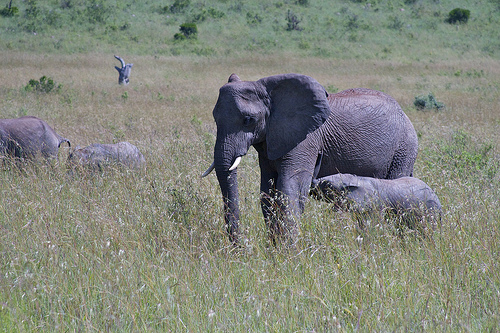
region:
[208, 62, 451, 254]
two elephants standing together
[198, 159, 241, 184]
white tusks of gray elephant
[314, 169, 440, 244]
baby elephant standing next to elephant with white tusks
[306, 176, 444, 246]
baby elephant nuzzling other elephant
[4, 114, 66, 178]
elephant next to gray rock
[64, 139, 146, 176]
large gray rock in field of long grass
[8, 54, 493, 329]
long grass elephants are walking through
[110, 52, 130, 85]
twisted trunk of dead tree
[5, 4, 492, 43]
field of green grass in background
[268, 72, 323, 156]
ear of larger elephant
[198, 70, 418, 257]
mother elephant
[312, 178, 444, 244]
baby elephant under mother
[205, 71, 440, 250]
mother nursing baby elephant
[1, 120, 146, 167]
two elephants hiding in the grass on left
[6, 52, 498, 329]
very tall grass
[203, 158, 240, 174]
tusks of mother elephant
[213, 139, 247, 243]
mother elephant's trunk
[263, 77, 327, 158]
mother elephant's big left ear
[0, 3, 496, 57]
green bushes on a hill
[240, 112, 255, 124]
the mother elephant's eye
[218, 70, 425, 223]
african elephant standing in grass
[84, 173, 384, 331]
tall green grass around elephants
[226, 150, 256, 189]
white ivory tusk on elephant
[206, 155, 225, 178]
white ivory tusk on elephant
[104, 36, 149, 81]
tree stump in tall grass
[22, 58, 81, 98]
green bushes in green grass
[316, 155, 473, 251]
small elephant getting milk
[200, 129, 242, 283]
long trunk of elephant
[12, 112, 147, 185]
two more elephants on left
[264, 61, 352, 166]
large elephant's ear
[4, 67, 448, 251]
Elephants in an open field.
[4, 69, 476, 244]
Elephants walking together in a field.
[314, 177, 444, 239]
Baby elephant walking next to its mother.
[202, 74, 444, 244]
An adult elephant with baby elephant beside it.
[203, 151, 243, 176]
Tusks on elephant's trunk.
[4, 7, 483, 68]
Green shrubs in the background.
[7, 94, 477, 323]
Tall green and brown grass on field.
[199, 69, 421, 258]
A grey adult elephant in a field.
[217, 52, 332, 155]
Elephants gigantic ear on the sides of head.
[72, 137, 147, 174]
A grey elephant walking in a field.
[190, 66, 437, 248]
two elephants standing by each other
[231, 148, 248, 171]
ivory tusk of elephants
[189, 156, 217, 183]
ivory tusk of elephant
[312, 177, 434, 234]
baby elephant standing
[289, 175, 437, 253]
baby elephant by large one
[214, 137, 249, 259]
long grey trunk of animal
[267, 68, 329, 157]
large grey ear of elephant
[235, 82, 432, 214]
large grey rugged body of elephant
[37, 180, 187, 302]
tall field of green grass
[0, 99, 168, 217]
small elephants in background